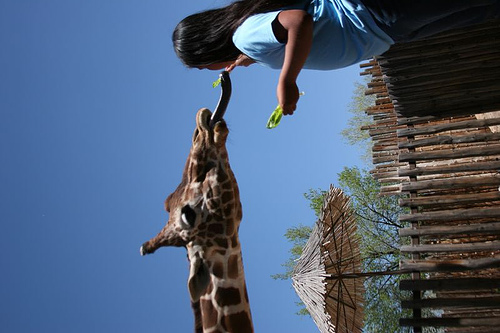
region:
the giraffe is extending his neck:
[144, 69, 260, 331]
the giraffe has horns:
[136, 208, 176, 257]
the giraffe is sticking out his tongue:
[207, 72, 232, 125]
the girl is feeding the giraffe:
[169, 6, 498, 123]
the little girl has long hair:
[166, 5, 322, 65]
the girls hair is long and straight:
[171, 2, 311, 63]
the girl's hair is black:
[170, 3, 306, 67]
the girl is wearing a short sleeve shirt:
[240, 2, 391, 77]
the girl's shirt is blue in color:
[237, 6, 382, 70]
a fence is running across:
[360, 65, 498, 326]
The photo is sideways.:
[4, 2, 496, 292]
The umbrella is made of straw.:
[283, 187, 357, 322]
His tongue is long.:
[180, 71, 251, 126]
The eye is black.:
[164, 193, 200, 240]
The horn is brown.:
[132, 216, 180, 271]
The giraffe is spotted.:
[90, 91, 250, 331]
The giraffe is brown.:
[95, 100, 273, 330]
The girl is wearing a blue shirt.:
[229, 2, 399, 83]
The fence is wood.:
[365, 55, 498, 316]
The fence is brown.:
[348, 49, 494, 329]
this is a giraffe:
[117, 98, 274, 328]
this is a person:
[172, 0, 437, 120]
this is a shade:
[271, 188, 442, 331]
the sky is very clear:
[49, 45, 160, 160]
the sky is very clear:
[64, 185, 128, 258]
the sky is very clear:
[14, 22, 114, 125]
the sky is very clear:
[59, 226, 103, 268]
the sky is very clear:
[249, 174, 293, 246]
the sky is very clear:
[26, 238, 114, 303]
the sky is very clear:
[84, 54, 158, 136]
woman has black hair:
[165, 32, 269, 64]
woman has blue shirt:
[219, 0, 376, 55]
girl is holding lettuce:
[212, 69, 297, 148]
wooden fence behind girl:
[340, 118, 490, 280]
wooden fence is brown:
[381, 31, 498, 298]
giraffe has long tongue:
[210, 74, 230, 146]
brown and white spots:
[192, 232, 258, 332]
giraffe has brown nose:
[155, 121, 229, 186]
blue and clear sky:
[57, 31, 89, 209]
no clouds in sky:
[40, 41, 156, 203]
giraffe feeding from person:
[151, 70, 289, 329]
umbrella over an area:
[282, 181, 397, 331]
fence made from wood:
[347, 62, 499, 322]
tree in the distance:
[280, 150, 417, 331]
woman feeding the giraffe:
[162, 1, 492, 111]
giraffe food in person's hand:
[254, 88, 309, 128]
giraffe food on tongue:
[210, 68, 239, 87]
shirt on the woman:
[229, 9, 393, 75]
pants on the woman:
[358, 5, 499, 52]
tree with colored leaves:
[339, 80, 381, 150]